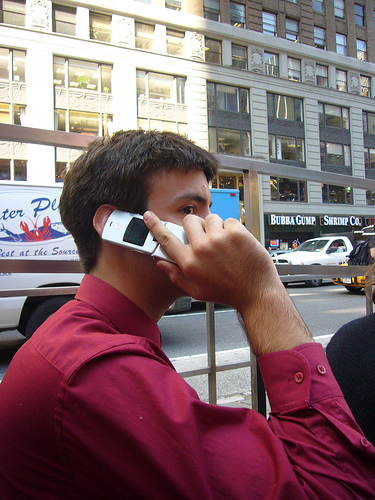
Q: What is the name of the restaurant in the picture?
A: Bubba Gump Shrimp Co.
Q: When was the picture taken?
A: During the day.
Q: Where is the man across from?
A: A building.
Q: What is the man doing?
A: Talking on the phone.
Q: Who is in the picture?
A: A man.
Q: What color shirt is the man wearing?
A: Red.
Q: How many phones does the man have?
A: One.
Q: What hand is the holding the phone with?
A: Right.